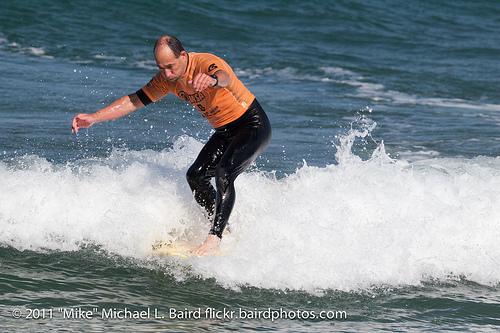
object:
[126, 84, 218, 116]
shadow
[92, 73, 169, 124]
arm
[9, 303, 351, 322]
writing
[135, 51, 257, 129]
shirt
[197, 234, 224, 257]
feet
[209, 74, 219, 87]
watch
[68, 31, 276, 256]
man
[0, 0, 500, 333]
ocean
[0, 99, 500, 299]
wave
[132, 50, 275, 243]
wetsuit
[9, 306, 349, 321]
description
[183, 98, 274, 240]
pants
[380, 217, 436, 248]
waves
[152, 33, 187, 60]
hair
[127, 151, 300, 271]
surfing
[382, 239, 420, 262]
white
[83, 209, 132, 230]
white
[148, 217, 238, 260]
surfboard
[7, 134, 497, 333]
water